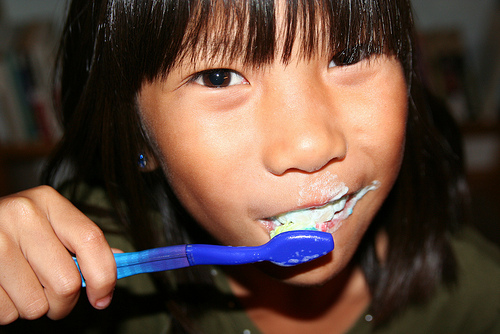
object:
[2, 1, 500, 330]
girl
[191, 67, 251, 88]
eye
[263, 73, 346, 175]
nose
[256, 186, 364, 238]
mouth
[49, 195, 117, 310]
finger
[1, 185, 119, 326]
hand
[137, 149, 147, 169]
earring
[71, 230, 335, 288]
toothbrush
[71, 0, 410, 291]
head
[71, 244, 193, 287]
handle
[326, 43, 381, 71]
eyes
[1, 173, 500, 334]
shirt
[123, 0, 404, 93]
bangs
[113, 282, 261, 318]
shadow of toothbrush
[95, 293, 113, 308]
fingernail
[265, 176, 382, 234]
toothpaste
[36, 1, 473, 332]
hair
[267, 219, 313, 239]
toothbrush bristles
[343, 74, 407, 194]
girl's cheek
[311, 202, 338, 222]
girl's teeth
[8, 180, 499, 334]
girl's shoulder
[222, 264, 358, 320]
shadow of chin